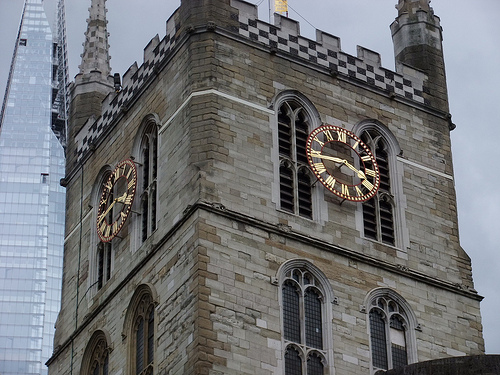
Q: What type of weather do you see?
A: It is cloudy.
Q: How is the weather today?
A: It is cloudy.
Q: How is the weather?
A: It is cloudy.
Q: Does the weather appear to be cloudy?
A: Yes, it is cloudy.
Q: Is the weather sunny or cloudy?
A: It is cloudy.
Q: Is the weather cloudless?
A: No, it is cloudy.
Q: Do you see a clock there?
A: Yes, there is a clock.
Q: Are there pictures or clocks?
A: Yes, there is a clock.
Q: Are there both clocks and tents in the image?
A: No, there is a clock but no tents.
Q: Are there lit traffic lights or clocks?
A: Yes, there is a lit clock.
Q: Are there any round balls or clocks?
A: Yes, there is a round clock.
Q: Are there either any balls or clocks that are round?
A: Yes, the clock is round.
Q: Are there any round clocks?
A: Yes, there is a round clock.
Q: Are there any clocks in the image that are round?
A: Yes, there is a clock that is round.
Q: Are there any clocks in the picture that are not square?
A: Yes, there is a round clock.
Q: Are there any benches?
A: No, there are no benches.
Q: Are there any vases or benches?
A: No, there are no benches or vases.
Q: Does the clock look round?
A: Yes, the clock is round.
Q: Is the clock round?
A: Yes, the clock is round.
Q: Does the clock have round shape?
A: Yes, the clock is round.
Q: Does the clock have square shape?
A: No, the clock is round.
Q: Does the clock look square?
A: No, the clock is round.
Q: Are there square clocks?
A: No, there is a clock but it is round.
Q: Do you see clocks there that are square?
A: No, there is a clock but it is round.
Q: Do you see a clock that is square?
A: No, there is a clock but it is round.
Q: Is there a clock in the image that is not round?
A: No, there is a clock but it is round.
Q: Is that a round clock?
A: Yes, that is a round clock.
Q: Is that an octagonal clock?
A: No, that is a round clock.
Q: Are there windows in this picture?
A: Yes, there are windows.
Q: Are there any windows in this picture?
A: Yes, there are windows.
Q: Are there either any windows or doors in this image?
A: Yes, there are windows.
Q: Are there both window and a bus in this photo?
A: No, there are windows but no buses.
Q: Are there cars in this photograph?
A: No, there are no cars.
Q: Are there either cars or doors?
A: No, there are no cars or doors.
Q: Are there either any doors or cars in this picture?
A: No, there are no cars or doors.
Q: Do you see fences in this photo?
A: No, there are no fences.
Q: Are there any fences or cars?
A: No, there are no fences or cars.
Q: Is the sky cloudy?
A: Yes, the sky is cloudy.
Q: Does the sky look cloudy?
A: Yes, the sky is cloudy.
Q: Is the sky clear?
A: No, the sky is cloudy.